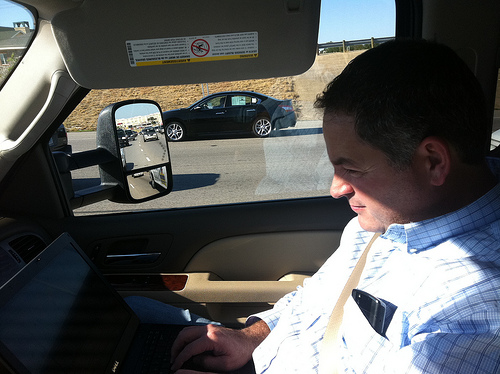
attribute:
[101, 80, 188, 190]
mirror — rearview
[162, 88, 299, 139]
car — black, on other side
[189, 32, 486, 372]
man — squinting, seat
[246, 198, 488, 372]
shirt — checkered, long sleeved, white, blue, plaid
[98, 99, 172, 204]
mirror — side view, side, large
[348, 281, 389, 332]
phone — black, cell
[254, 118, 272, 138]
wheel — rear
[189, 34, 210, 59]
symbol — airbag warning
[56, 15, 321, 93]
visor — sun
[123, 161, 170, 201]
mirror — spot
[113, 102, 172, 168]
mirror — main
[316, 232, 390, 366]
neck tie — tan, fabric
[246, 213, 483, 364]
shirt — white, button down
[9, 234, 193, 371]
laptop — black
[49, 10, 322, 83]
visor — tan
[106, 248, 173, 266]
handle — silver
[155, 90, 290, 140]
car — black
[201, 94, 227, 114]
window — glass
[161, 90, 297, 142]
car — black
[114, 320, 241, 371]
laptop keyboard — black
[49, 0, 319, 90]
sun visor — beige, functioning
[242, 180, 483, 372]
shirt — white